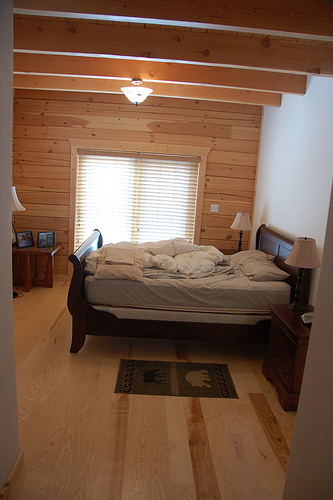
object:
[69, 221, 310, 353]
bed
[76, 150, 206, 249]
blinds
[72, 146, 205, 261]
window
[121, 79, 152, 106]
light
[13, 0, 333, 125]
ceiling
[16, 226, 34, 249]
picture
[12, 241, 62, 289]
table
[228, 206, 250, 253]
lampshade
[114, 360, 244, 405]
rug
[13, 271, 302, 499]
floor